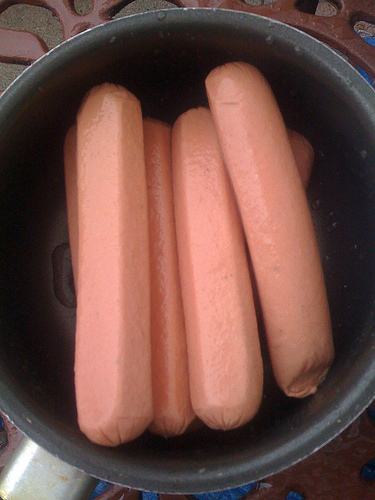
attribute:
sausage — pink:
[64, 124, 77, 290]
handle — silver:
[2, 425, 88, 498]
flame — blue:
[95, 491, 261, 499]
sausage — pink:
[73, 85, 151, 498]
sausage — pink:
[206, 55, 336, 405]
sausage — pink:
[164, 94, 256, 487]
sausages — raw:
[52, 57, 249, 462]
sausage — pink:
[72, 79, 157, 450]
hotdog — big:
[75, 81, 151, 446]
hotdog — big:
[171, 102, 261, 428]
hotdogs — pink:
[106, 107, 263, 319]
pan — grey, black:
[0, 10, 370, 487]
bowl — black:
[131, 446, 246, 498]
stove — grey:
[275, 4, 374, 54]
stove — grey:
[4, 3, 118, 44]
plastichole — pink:
[350, 12, 374, 43]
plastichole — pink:
[293, 0, 343, 17]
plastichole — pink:
[0, 3, 61, 47]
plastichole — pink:
[105, 1, 185, 12]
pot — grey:
[4, 10, 360, 499]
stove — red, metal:
[0, 0, 373, 90]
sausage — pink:
[66, 98, 329, 458]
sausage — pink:
[53, 63, 348, 401]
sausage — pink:
[194, 83, 331, 387]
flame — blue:
[193, 482, 251, 498]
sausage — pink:
[172, 85, 373, 377]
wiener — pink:
[169, 103, 263, 431]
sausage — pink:
[143, 120, 194, 435]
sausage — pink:
[174, 106, 264, 431]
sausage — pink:
[145, 119, 198, 442]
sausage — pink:
[79, 79, 153, 447]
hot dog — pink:
[172, 99, 268, 426]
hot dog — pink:
[143, 118, 195, 440]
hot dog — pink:
[203, 63, 340, 399]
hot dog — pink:
[72, 82, 153, 446]